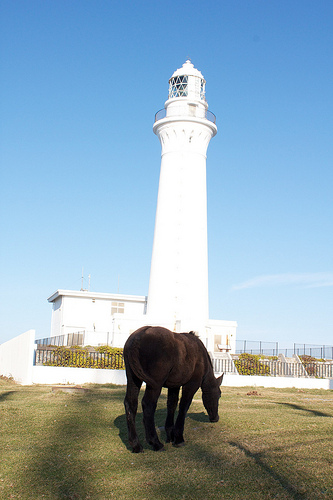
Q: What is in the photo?
A: A horse.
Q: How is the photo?
A: Clear.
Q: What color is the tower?
A: White.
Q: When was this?
A: Daytime.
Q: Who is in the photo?
A: Nobody.